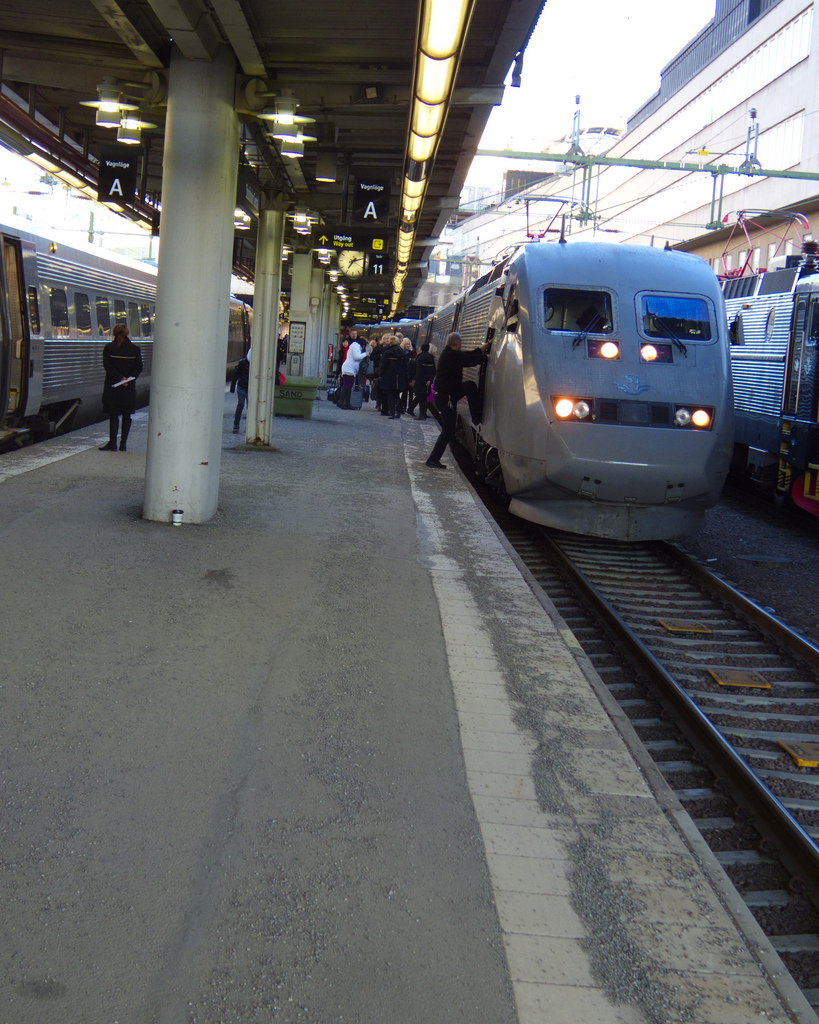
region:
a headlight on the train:
[592, 335, 628, 368]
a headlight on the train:
[640, 339, 657, 368]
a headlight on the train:
[557, 397, 574, 422]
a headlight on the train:
[575, 399, 591, 420]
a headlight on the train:
[676, 404, 688, 432]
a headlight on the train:
[699, 409, 708, 430]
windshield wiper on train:
[578, 285, 614, 350]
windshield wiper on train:
[647, 299, 690, 350]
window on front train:
[538, 280, 616, 337]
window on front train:
[644, 289, 714, 340]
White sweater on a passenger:
[338, 336, 373, 382]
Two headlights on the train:
[590, 335, 664, 365]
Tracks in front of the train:
[522, 504, 816, 870]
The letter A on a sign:
[353, 197, 385, 225]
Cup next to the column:
[170, 509, 184, 532]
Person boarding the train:
[421, 322, 500, 481]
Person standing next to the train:
[98, 312, 148, 452]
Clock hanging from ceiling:
[334, 246, 370, 277]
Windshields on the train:
[537, 270, 723, 349]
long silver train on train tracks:
[348, 230, 746, 569]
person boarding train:
[420, 327, 497, 475]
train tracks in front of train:
[511, 531, 815, 1022]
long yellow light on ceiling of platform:
[372, 1, 477, 327]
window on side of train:
[42, 283, 77, 342]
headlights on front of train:
[545, 389, 720, 435]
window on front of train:
[534, 281, 618, 341]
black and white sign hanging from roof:
[344, 172, 393, 230]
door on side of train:
[468, 320, 504, 427]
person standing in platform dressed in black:
[91, 317, 148, 456]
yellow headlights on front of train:
[545, 386, 725, 446]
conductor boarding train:
[413, 320, 499, 476]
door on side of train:
[461, 323, 501, 428]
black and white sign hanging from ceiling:
[343, 172, 392, 231]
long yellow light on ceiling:
[376, 1, 484, 326]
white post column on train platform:
[138, 47, 245, 531]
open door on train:
[1, 229, 38, 433]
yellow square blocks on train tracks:
[646, 604, 779, 703]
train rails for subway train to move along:
[532, 522, 816, 901]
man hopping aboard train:
[421, 330, 497, 475]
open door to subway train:
[0, 233, 35, 434]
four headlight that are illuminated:
[548, 338, 715, 428]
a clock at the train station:
[338, 248, 364, 278]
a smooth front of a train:
[490, 241, 735, 546]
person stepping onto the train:
[423, 335, 481, 470]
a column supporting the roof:
[135, 58, 252, 522]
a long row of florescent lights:
[381, 0, 469, 322]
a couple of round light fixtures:
[259, 96, 312, 149]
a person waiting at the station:
[90, 324, 137, 453]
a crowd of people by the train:
[324, 330, 448, 418]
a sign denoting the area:
[354, 175, 389, 227]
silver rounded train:
[417, 222, 732, 547]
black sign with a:
[94, 160, 134, 202]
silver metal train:
[7, 222, 189, 461]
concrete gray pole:
[127, 36, 251, 540]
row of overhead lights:
[377, 9, 468, 341]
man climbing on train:
[421, 319, 494, 473]